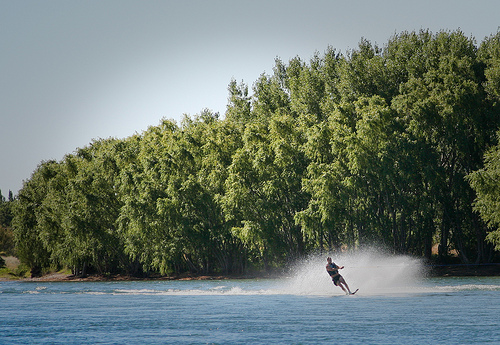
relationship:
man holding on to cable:
[326, 256, 353, 295] [343, 262, 499, 269]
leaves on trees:
[251, 107, 393, 175] [253, 50, 481, 182]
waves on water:
[85, 276, 497, 292] [1, 238, 497, 343]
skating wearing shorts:
[324, 256, 359, 294] [319, 259, 346, 298]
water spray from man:
[275, 243, 430, 294] [326, 256, 353, 295]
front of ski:
[351, 287, 360, 296] [350, 288, 359, 294]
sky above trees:
[2, 2, 495, 61] [8, 27, 499, 277]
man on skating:
[326, 256, 353, 295] [324, 256, 359, 294]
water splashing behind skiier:
[291, 250, 430, 294] [324, 253, 359, 297]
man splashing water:
[326, 256, 353, 295] [0, 274, 499, 344]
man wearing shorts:
[326, 256, 353, 295] [331, 269, 342, 284]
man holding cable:
[326, 256, 353, 295] [343, 261, 499, 268]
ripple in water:
[112, 309, 372, 328] [4, 279, 499, 341]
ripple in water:
[340, 320, 432, 340] [0, 274, 499, 344]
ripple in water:
[2, 320, 96, 335] [0, 274, 499, 344]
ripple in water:
[1, 297, 159, 318] [0, 274, 499, 344]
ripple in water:
[326, 301, 497, 319] [0, 274, 499, 344]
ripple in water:
[329, 317, 451, 332] [0, 274, 499, 344]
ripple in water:
[166, 300, 235, 319] [0, 274, 499, 344]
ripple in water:
[232, 310, 464, 331] [0, 274, 499, 344]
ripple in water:
[299, 295, 496, 304] [0, 274, 499, 344]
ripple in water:
[0, 317, 160, 330] [0, 274, 499, 344]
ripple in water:
[4, 332, 61, 344] [0, 274, 499, 344]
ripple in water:
[141, 300, 251, 316] [0, 274, 499, 344]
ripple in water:
[212, 282, 274, 302] [0, 274, 499, 344]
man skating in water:
[326, 254, 359, 299] [0, 274, 499, 344]